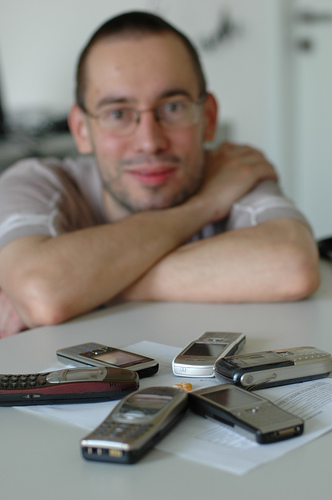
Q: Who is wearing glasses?
A: The man.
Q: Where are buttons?
A: On cell phones.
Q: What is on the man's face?
A: Glasses.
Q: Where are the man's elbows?
A: On the table.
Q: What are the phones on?
A: Piece of paper.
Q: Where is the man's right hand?
A: On his shoulder.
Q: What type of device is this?
A: Mobile phone.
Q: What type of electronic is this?
A: Cellular phone.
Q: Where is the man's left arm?
A: On the table.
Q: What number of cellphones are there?
A: Six.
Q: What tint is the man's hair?
A: Dark.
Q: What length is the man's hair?
A: Short.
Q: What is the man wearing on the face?
A: Glasses.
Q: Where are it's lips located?
A: Under his nose.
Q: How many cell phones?
A: Six.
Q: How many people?
A: One.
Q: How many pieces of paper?
A: One.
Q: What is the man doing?
A: Leaning on table.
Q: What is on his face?
A: Glasses.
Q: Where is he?
A: Home.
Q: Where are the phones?
A: On the table.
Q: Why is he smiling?
A: Happy.